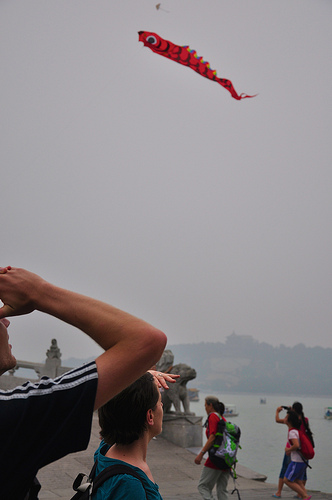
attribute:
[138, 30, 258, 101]
kite — long, red, in the sky, dragon, black, fish, large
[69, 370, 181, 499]
person — up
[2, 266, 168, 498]
person — up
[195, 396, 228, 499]
person — in background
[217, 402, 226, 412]
person — in background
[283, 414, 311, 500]
person — in background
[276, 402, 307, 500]
person — in background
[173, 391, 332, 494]
ocean — in background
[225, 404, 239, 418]
boat — small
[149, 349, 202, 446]
statue — animal, made of stone, in background, stone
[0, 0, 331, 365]
sky — cloudy, above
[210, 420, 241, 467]
backpack — colorful, person's, green, black, white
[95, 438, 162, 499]
shirt — blue, dark teal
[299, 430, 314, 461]
backpack — red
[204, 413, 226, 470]
shirt — red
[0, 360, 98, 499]
shirt — striped, black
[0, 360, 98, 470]
sleeve — short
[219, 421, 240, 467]
baby dress — green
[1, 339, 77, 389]
railing — stone